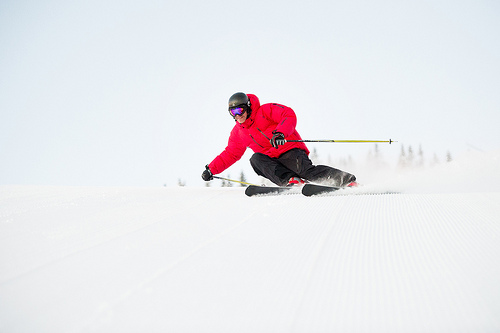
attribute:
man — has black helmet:
[196, 84, 384, 201]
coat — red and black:
[198, 90, 402, 200]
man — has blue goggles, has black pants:
[197, 88, 403, 198]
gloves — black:
[270, 129, 287, 158]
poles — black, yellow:
[289, 134, 395, 150]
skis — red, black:
[200, 158, 349, 205]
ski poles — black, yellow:
[277, 119, 411, 168]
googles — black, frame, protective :
[220, 101, 249, 119]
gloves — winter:
[174, 138, 294, 162]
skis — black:
[224, 174, 355, 191]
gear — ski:
[201, 90, 342, 201]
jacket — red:
[177, 116, 305, 156]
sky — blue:
[80, 73, 163, 128]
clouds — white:
[124, 70, 182, 149]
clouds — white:
[112, 59, 185, 141]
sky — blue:
[136, 46, 147, 83]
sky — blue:
[7, 73, 68, 108]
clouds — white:
[113, 79, 149, 129]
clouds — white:
[27, 58, 67, 104]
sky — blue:
[62, 27, 105, 64]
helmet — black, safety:
[210, 91, 255, 113]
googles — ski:
[225, 105, 246, 117]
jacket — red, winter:
[215, 110, 320, 157]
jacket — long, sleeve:
[207, 122, 315, 156]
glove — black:
[199, 170, 211, 182]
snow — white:
[1, 2, 499, 331]